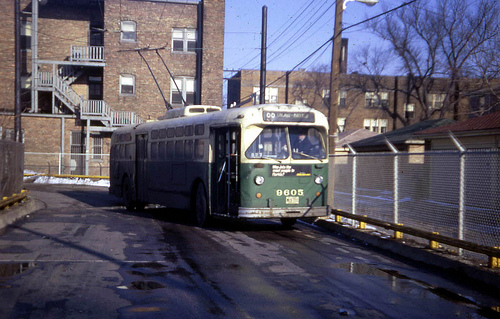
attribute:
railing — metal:
[67, 44, 103, 61]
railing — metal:
[36, 70, 81, 106]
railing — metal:
[78, 98, 111, 118]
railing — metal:
[107, 109, 144, 127]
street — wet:
[1, 184, 499, 316]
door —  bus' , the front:
[201, 118, 245, 222]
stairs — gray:
[33, 46, 115, 128]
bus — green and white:
[106, 103, 328, 228]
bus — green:
[102, 94, 336, 235]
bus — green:
[115, 127, 322, 234]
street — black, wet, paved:
[0, 167, 495, 316]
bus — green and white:
[105, 94, 330, 223]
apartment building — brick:
[234, 67, 489, 172]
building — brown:
[2, 4, 273, 213]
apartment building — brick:
[1, 2, 228, 173]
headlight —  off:
[253, 174, 264, 184]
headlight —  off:
[314, 175, 324, 185]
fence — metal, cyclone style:
[320, 99, 496, 269]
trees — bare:
[357, 0, 499, 109]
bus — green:
[108, 101, 332, 218]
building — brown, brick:
[104, 7, 194, 61]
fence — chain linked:
[316, 145, 485, 253]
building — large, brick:
[4, 0, 224, 177]